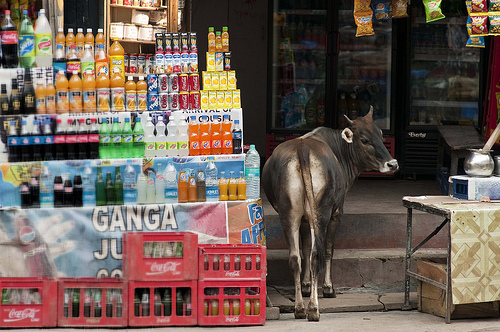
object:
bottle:
[245, 144, 261, 199]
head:
[341, 105, 400, 174]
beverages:
[0, 0, 266, 329]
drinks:
[18, 10, 36, 69]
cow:
[260, 105, 399, 322]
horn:
[344, 114, 355, 126]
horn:
[364, 105, 374, 118]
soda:
[21, 67, 37, 114]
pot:
[464, 148, 495, 178]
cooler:
[399, 0, 500, 165]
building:
[0, 0, 500, 328]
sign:
[91, 203, 179, 278]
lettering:
[91, 204, 179, 232]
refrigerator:
[265, 0, 402, 180]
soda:
[215, 31, 222, 52]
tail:
[298, 148, 327, 278]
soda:
[216, 90, 227, 109]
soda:
[147, 74, 159, 93]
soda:
[55, 70, 68, 114]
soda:
[76, 118, 90, 160]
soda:
[30, 120, 43, 161]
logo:
[20, 226, 36, 243]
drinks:
[125, 75, 137, 111]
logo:
[224, 270, 240, 277]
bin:
[199, 244, 267, 281]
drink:
[244, 144, 260, 201]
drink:
[114, 164, 124, 205]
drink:
[108, 37, 125, 86]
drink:
[35, 9, 55, 69]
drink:
[53, 165, 64, 207]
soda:
[99, 117, 111, 159]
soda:
[110, 117, 121, 159]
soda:
[200, 115, 211, 155]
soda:
[155, 116, 166, 158]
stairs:
[265, 210, 447, 313]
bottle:
[208, 27, 215, 52]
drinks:
[190, 73, 200, 92]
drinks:
[110, 68, 125, 111]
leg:
[322, 203, 343, 285]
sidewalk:
[262, 297, 444, 331]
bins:
[122, 231, 199, 281]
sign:
[6, 307, 41, 322]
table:
[0, 198, 266, 277]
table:
[401, 195, 499, 324]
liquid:
[188, 119, 199, 156]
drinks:
[196, 162, 206, 202]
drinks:
[155, 162, 165, 204]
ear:
[341, 128, 354, 144]